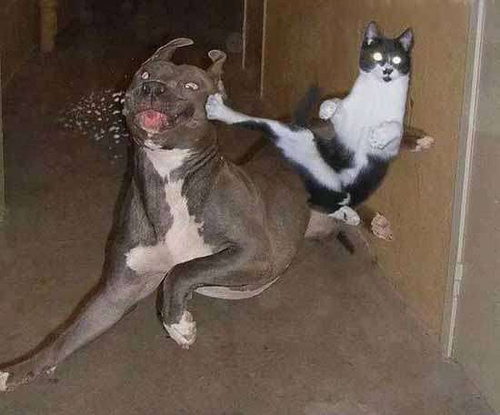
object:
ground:
[0, 51, 499, 415]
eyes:
[372, 52, 381, 60]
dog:
[1, 37, 436, 394]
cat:
[207, 22, 414, 226]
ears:
[365, 22, 380, 43]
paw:
[329, 206, 359, 225]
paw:
[156, 307, 196, 345]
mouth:
[134, 109, 168, 132]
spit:
[60, 89, 124, 142]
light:
[392, 57, 401, 64]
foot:
[205, 93, 223, 120]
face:
[126, 61, 214, 148]